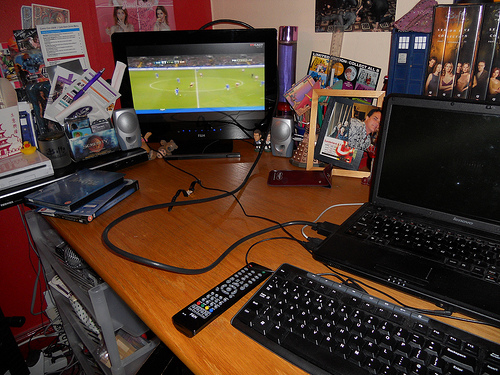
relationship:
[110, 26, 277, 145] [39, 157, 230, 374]
monitor for a desktop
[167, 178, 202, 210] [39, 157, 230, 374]
wristwatch on desk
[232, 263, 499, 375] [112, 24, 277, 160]
keyboard for a computer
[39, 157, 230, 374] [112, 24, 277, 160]
desk has a monitor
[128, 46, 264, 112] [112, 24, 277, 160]
soccer game on monitor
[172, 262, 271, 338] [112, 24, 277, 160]
remote for tv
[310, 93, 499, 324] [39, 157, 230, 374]
black laptop on desk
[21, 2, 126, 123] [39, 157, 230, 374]
messy papers on desk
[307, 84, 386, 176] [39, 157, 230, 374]
photo on desk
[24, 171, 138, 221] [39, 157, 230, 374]
dvd's on desk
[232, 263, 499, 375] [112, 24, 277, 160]
keyboard for a desktop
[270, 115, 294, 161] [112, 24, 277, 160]
speakers are for a computer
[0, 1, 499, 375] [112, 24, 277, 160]
room for a computer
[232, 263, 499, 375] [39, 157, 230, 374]
keyboard on desk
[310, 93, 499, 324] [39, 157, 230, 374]
laptop on desk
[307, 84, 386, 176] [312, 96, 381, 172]
frame for pictures